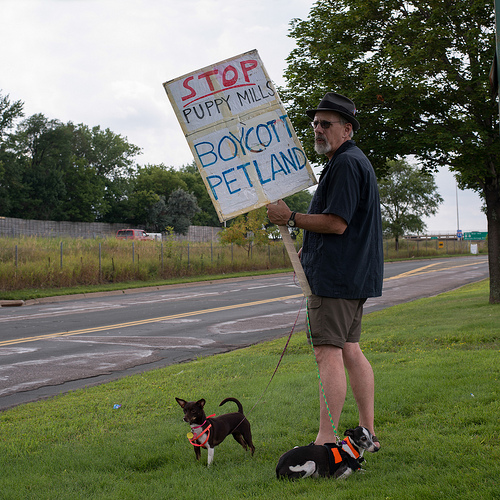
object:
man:
[266, 94, 382, 448]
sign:
[162, 48, 319, 224]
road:
[1, 254, 496, 407]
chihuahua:
[175, 397, 256, 469]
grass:
[4, 276, 497, 498]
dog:
[276, 427, 380, 486]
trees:
[0, 92, 314, 219]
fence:
[1, 218, 262, 245]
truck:
[117, 230, 156, 243]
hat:
[305, 93, 362, 129]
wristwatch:
[288, 211, 296, 227]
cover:
[113, 234, 132, 237]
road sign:
[466, 231, 487, 243]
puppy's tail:
[218, 399, 243, 413]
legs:
[316, 342, 376, 439]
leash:
[229, 293, 310, 434]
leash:
[305, 302, 343, 447]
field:
[3, 238, 438, 291]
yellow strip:
[0, 255, 245, 355]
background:
[434, 170, 489, 254]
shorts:
[308, 291, 367, 348]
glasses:
[311, 120, 334, 132]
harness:
[325, 437, 363, 471]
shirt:
[300, 141, 385, 298]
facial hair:
[313, 133, 331, 156]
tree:
[278, 0, 498, 306]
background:
[0, 93, 485, 228]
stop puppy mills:
[180, 59, 278, 123]